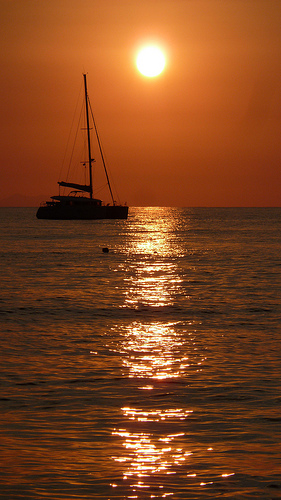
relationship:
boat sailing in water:
[36, 72, 129, 222] [16, 216, 144, 234]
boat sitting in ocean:
[36, 72, 129, 222] [14, 213, 138, 236]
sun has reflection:
[132, 39, 169, 80] [104, 203, 196, 498]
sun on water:
[132, 39, 169, 80] [0, 207, 280, 499]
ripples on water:
[0, 356, 281, 423] [12, 268, 275, 452]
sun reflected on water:
[96, 411, 195, 489] [158, 428, 239, 480]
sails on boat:
[56, 178, 89, 194] [36, 72, 129, 222]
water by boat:
[0, 207, 280, 499] [36, 72, 129, 222]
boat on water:
[36, 72, 129, 222] [164, 231, 196, 251]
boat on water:
[36, 72, 129, 222] [49, 219, 120, 266]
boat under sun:
[36, 72, 129, 222] [129, 39, 169, 80]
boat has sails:
[36, 72, 129, 222] [57, 181, 91, 192]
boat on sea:
[36, 72, 129, 222] [1, 202, 279, 497]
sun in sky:
[132, 39, 169, 80] [2, 0, 279, 204]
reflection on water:
[121, 211, 182, 316] [234, 217, 270, 279]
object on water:
[101, 245, 111, 254] [0, 207, 280, 499]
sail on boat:
[58, 181, 92, 191] [36, 72, 129, 222]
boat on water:
[36, 72, 129, 222] [25, 232, 255, 300]